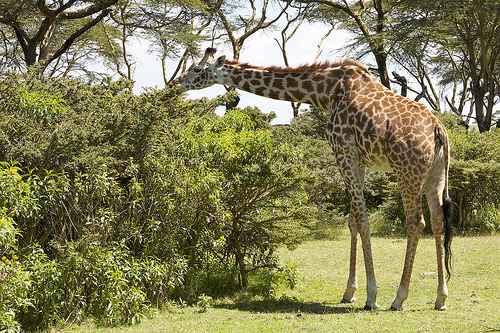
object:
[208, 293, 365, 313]
shadow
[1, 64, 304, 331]
bush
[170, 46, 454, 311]
giraffe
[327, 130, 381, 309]
leg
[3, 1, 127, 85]
tree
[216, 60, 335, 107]
neck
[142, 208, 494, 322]
lawn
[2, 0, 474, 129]
sky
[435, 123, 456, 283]
tail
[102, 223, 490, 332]
grass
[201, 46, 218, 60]
horns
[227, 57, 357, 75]
hair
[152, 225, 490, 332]
ground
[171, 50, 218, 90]
head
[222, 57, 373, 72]
mane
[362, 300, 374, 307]
feet